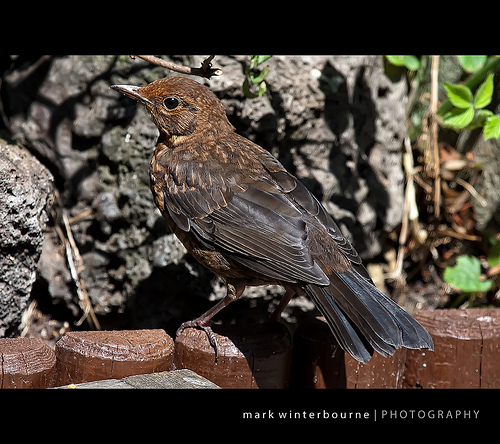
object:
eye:
[162, 98, 183, 109]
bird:
[109, 73, 437, 367]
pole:
[176, 324, 289, 389]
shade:
[212, 308, 350, 391]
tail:
[309, 262, 436, 364]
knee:
[225, 281, 247, 301]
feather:
[344, 277, 382, 353]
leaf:
[249, 54, 272, 94]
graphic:
[240, 401, 489, 424]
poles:
[407, 309, 499, 392]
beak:
[110, 81, 143, 97]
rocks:
[0, 141, 58, 337]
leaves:
[443, 78, 478, 109]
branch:
[130, 54, 223, 79]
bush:
[382, 52, 495, 294]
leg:
[200, 288, 246, 333]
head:
[109, 76, 235, 137]